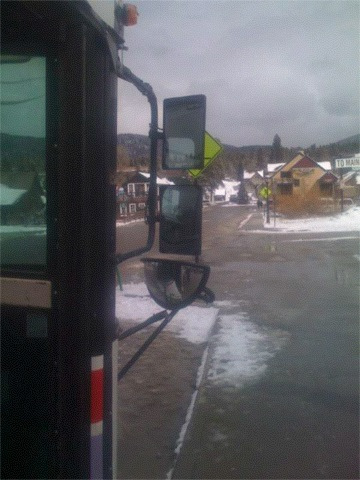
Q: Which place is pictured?
A: It is a road.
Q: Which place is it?
A: It is a road.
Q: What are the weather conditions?
A: It is cloudy.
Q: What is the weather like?
A: It is cloudy.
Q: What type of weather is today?
A: It is cloudy.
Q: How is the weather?
A: It is cloudy.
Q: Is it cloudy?
A: Yes, it is cloudy.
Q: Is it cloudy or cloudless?
A: It is cloudy.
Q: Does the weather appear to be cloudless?
A: No, it is cloudy.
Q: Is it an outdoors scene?
A: Yes, it is outdoors.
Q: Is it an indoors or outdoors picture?
A: It is outdoors.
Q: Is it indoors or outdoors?
A: It is outdoors.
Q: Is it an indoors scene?
A: No, it is outdoors.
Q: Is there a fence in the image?
A: No, there are no fences.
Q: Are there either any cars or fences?
A: No, there are no cars or fences.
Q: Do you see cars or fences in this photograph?
A: No, there are no cars or fences.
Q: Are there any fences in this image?
A: No, there are no fences.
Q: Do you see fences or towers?
A: No, there are no fences or towers.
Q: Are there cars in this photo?
A: No, there are no cars.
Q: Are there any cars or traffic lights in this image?
A: No, there are no cars or traffic lights.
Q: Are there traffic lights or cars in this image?
A: No, there are no cars or traffic lights.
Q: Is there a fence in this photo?
A: No, there are no fences.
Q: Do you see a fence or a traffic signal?
A: No, there are no fences or traffic lights.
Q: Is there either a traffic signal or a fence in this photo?
A: No, there are no fences or traffic lights.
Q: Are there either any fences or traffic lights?
A: No, there are no fences or traffic lights.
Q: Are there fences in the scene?
A: No, there are no fences.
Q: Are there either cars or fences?
A: No, there are no fences or cars.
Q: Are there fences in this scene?
A: No, there are no fences.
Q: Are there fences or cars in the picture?
A: No, there are no fences or cars.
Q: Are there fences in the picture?
A: No, there are no fences.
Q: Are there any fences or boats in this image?
A: No, there are no fences or boats.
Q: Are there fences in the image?
A: No, there are no fences.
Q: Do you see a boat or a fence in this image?
A: No, there are no fences or boats.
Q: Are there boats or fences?
A: No, there are no fences or boats.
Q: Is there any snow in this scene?
A: Yes, there is snow.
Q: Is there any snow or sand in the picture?
A: Yes, there is snow.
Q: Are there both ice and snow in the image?
A: Yes, there are both snow and ice.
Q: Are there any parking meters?
A: No, there are no parking meters.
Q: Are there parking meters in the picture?
A: No, there are no parking meters.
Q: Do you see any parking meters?
A: No, there are no parking meters.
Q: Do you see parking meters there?
A: No, there are no parking meters.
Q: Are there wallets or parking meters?
A: No, there are no parking meters or wallets.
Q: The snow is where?
A: The snow is on the road.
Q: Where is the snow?
A: The snow is on the road.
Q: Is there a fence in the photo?
A: No, there are no fences.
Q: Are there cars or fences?
A: No, there are no fences or cars.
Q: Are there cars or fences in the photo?
A: No, there are no cars or fences.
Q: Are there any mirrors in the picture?
A: Yes, there is a mirror.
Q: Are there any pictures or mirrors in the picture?
A: Yes, there is a mirror.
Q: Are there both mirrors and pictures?
A: No, there is a mirror but no pictures.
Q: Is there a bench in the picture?
A: No, there are no benches.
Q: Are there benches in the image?
A: No, there are no benches.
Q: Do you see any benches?
A: No, there are no benches.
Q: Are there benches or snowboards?
A: No, there are no benches or snowboards.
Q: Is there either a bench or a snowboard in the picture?
A: No, there are no benches or snowboards.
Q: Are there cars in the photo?
A: No, there are no cars.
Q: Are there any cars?
A: No, there are no cars.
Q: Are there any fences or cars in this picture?
A: No, there are no cars or fences.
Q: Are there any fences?
A: No, there are no fences.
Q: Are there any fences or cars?
A: No, there are no fences or cars.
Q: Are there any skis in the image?
A: No, there are no skis.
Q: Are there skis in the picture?
A: No, there are no skis.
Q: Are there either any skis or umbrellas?
A: No, there are no skis or umbrellas.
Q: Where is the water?
A: The water is on the street.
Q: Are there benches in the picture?
A: No, there are no benches.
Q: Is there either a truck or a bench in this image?
A: No, there are no benches or trucks.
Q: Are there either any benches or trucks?
A: No, there are no benches or trucks.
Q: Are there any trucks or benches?
A: No, there are no benches or trucks.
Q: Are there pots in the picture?
A: No, there are no pots.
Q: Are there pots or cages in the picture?
A: No, there are no pots or cages.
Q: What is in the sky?
A: The clouds are in the sky.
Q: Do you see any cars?
A: No, there are no cars.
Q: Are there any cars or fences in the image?
A: No, there are no cars or fences.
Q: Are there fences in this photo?
A: No, there are no fences.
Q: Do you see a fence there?
A: No, there are no fences.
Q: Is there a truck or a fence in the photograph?
A: No, there are no fences or trucks.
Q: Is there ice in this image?
A: Yes, there is ice.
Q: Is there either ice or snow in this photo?
A: Yes, there is ice.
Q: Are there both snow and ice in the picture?
A: Yes, there are both ice and snow.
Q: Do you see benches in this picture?
A: No, there are no benches.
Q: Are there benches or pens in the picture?
A: No, there are no benches or pens.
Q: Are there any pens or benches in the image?
A: No, there are no benches or pens.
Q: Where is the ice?
A: The ice is on the road.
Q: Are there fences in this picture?
A: No, there are no fences.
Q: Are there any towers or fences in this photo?
A: No, there are no fences or towers.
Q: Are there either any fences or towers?
A: No, there are no fences or towers.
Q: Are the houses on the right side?
A: Yes, the houses are on the right of the image.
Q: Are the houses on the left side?
A: No, the houses are on the right of the image.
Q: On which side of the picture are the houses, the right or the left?
A: The houses are on the right of the image.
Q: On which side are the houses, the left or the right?
A: The houses are on the right of the image.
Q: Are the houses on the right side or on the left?
A: The houses are on the right of the image.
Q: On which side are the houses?
A: The houses are on the right of the image.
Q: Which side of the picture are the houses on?
A: The houses are on the right of the image.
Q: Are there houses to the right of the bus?
A: Yes, there are houses to the right of the bus.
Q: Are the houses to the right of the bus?
A: Yes, the houses are to the right of the bus.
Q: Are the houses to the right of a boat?
A: No, the houses are to the right of the bus.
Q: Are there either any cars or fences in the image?
A: No, there are no cars or fences.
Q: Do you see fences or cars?
A: No, there are no cars or fences.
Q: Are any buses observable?
A: Yes, there is a bus.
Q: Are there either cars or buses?
A: Yes, there is a bus.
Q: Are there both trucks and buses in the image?
A: No, there is a bus but no trucks.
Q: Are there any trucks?
A: No, there are no trucks.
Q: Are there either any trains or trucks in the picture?
A: No, there are no trucks or trains.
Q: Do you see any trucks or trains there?
A: No, there are no trucks or trains.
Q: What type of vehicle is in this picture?
A: The vehicle is a bus.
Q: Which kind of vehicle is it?
A: The vehicle is a bus.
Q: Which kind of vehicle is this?
A: This is a bus.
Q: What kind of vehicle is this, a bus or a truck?
A: This is a bus.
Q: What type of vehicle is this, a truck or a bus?
A: This is a bus.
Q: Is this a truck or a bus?
A: This is a bus.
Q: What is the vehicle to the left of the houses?
A: The vehicle is a bus.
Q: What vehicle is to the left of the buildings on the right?
A: The vehicle is a bus.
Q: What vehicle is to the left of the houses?
A: The vehicle is a bus.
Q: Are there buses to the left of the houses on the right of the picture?
A: Yes, there is a bus to the left of the houses.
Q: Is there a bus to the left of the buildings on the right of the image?
A: Yes, there is a bus to the left of the houses.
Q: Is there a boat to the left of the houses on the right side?
A: No, there is a bus to the left of the houses.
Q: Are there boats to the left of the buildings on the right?
A: No, there is a bus to the left of the houses.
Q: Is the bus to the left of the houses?
A: Yes, the bus is to the left of the houses.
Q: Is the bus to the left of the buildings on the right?
A: Yes, the bus is to the left of the houses.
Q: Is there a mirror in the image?
A: Yes, there is a mirror.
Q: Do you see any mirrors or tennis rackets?
A: Yes, there is a mirror.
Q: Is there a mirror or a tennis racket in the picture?
A: Yes, there is a mirror.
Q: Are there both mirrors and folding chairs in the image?
A: No, there is a mirror but no folding chairs.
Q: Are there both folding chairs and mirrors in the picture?
A: No, there is a mirror but no folding chairs.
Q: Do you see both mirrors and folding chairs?
A: No, there is a mirror but no folding chairs.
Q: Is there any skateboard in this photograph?
A: No, there are no skateboards.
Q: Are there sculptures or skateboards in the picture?
A: No, there are no skateboards or sculptures.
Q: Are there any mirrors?
A: Yes, there is a mirror.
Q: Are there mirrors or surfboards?
A: Yes, there is a mirror.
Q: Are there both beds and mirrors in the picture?
A: No, there is a mirror but no beds.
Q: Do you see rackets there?
A: No, there are no rackets.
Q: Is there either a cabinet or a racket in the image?
A: No, there are no rackets or cabinets.